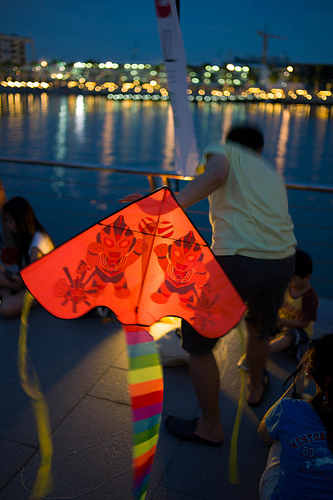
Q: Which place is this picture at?
A: It is at the shore.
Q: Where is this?
A: This is at the shore.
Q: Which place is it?
A: It is a shore.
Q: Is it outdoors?
A: Yes, it is outdoors.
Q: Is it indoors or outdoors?
A: It is outdoors.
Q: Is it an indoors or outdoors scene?
A: It is outdoors.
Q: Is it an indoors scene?
A: No, it is outdoors.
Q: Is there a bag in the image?
A: No, there are no bags.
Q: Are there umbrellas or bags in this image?
A: No, there are no bags or umbrellas.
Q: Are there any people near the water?
A: Yes, there are people near the water.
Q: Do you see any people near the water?
A: Yes, there are people near the water.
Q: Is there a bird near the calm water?
A: No, there are people near the water.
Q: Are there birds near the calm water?
A: No, there are people near the water.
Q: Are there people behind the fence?
A: Yes, there are people behind the fence.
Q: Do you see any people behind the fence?
A: Yes, there are people behind the fence.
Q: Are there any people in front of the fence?
A: No, the people are behind the fence.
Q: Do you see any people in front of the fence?
A: No, the people are behind the fence.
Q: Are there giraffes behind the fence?
A: No, there are people behind the fence.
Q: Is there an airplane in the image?
A: No, there are no airplanes.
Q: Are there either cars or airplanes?
A: No, there are no airplanes or cars.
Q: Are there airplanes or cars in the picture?
A: No, there are no airplanes or cars.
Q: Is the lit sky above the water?
A: Yes, the sky is above the water.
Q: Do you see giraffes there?
A: No, there are no giraffes.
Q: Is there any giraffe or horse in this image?
A: No, there are no giraffes or horses.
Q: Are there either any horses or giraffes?
A: No, there are no giraffes or horses.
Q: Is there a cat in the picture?
A: No, there are no cats.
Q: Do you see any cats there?
A: No, there are no cats.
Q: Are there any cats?
A: No, there are no cats.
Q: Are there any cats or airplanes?
A: No, there are no cats or airplanes.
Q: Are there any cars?
A: No, there are no cars.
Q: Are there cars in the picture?
A: No, there are no cars.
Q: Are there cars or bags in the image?
A: No, there are no cars or bags.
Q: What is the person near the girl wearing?
A: The person is wearing sandals.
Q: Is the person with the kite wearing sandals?
A: Yes, the person is wearing sandals.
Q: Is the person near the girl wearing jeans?
A: No, the person is wearing sandals.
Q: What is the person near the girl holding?
A: The person is holding the kite.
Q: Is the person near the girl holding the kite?
A: Yes, the person is holding the kite.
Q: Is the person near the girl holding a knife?
A: No, the person is holding the kite.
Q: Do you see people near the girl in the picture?
A: Yes, there is a person near the girl.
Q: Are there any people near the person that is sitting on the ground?
A: Yes, there is a person near the girl.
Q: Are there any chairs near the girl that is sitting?
A: No, there is a person near the girl.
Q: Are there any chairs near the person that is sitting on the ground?
A: No, there is a person near the girl.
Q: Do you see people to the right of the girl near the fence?
A: Yes, there is a person to the right of the girl.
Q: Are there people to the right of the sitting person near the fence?
A: Yes, there is a person to the right of the girl.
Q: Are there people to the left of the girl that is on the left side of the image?
A: No, the person is to the right of the girl.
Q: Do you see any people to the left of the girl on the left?
A: No, the person is to the right of the girl.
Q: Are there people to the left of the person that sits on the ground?
A: No, the person is to the right of the girl.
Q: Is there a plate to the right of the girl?
A: No, there is a person to the right of the girl.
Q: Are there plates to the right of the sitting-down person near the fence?
A: No, there is a person to the right of the girl.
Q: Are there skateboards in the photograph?
A: No, there are no skateboards.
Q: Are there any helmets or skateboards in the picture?
A: No, there are no skateboards or helmets.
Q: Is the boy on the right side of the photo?
A: Yes, the boy is on the right of the image.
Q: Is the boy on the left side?
A: No, the boy is on the right of the image.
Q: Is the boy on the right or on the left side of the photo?
A: The boy is on the right of the image.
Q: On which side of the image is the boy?
A: The boy is on the right of the image.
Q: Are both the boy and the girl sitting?
A: Yes, both the boy and the girl are sitting.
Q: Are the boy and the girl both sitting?
A: Yes, both the boy and the girl are sitting.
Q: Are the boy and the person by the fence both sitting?
A: Yes, both the boy and the girl are sitting.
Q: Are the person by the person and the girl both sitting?
A: Yes, both the boy and the girl are sitting.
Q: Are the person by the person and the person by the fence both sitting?
A: Yes, both the boy and the girl are sitting.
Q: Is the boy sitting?
A: Yes, the boy is sitting.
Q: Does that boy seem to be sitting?
A: Yes, the boy is sitting.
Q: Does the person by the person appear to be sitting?
A: Yes, the boy is sitting.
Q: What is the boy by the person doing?
A: The boy is sitting.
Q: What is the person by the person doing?
A: The boy is sitting.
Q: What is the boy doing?
A: The boy is sitting.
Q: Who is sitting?
A: The boy is sitting.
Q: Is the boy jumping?
A: No, the boy is sitting.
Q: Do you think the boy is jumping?
A: No, the boy is sitting.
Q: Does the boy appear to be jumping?
A: No, the boy is sitting.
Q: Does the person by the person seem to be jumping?
A: No, the boy is sitting.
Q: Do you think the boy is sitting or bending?
A: The boy is sitting.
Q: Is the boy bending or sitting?
A: The boy is sitting.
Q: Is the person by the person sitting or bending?
A: The boy is sitting.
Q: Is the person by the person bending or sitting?
A: The boy is sitting.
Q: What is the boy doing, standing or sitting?
A: The boy is sitting.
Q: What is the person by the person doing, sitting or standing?
A: The boy is sitting.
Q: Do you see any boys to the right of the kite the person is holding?
A: Yes, there is a boy to the right of the kite.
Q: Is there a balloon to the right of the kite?
A: No, there is a boy to the right of the kite.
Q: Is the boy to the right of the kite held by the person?
A: Yes, the boy is to the right of the kite.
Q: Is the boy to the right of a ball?
A: No, the boy is to the right of the kite.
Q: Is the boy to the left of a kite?
A: No, the boy is to the right of a kite.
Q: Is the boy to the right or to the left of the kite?
A: The boy is to the right of the kite.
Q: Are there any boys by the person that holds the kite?
A: Yes, there is a boy by the person.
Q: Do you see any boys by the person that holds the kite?
A: Yes, there is a boy by the person.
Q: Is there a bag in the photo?
A: No, there are no bags.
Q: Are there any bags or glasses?
A: No, there are no bags or glasses.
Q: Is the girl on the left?
A: Yes, the girl is on the left of the image.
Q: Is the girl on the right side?
A: No, the girl is on the left of the image.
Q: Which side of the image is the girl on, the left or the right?
A: The girl is on the left of the image.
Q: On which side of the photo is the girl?
A: The girl is on the left of the image.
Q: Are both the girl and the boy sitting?
A: Yes, both the girl and the boy are sitting.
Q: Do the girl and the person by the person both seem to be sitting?
A: Yes, both the girl and the boy are sitting.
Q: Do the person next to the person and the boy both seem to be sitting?
A: Yes, both the girl and the boy are sitting.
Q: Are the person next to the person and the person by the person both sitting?
A: Yes, both the girl and the boy are sitting.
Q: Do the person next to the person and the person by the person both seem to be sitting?
A: Yes, both the girl and the boy are sitting.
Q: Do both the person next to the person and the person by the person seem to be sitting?
A: Yes, both the girl and the boy are sitting.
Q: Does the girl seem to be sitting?
A: Yes, the girl is sitting.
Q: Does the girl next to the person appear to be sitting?
A: Yes, the girl is sitting.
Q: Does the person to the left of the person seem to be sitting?
A: Yes, the girl is sitting.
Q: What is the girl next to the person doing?
A: The girl is sitting.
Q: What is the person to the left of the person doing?
A: The girl is sitting.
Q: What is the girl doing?
A: The girl is sitting.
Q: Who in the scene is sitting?
A: The girl is sitting.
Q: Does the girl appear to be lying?
A: No, the girl is sitting.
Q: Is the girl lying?
A: No, the girl is sitting.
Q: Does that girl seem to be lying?
A: No, the girl is sitting.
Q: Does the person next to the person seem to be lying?
A: No, the girl is sitting.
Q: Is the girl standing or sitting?
A: The girl is sitting.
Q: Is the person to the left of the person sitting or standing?
A: The girl is sitting.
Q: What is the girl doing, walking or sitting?
A: The girl is sitting.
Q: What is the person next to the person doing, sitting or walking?
A: The girl is sitting.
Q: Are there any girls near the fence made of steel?
A: Yes, there is a girl near the fence.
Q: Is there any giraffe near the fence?
A: No, there is a girl near the fence.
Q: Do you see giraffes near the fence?
A: No, there is a girl near the fence.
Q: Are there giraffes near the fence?
A: No, there is a girl near the fence.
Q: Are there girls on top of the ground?
A: Yes, there is a girl on top of the ground.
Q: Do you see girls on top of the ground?
A: Yes, there is a girl on top of the ground.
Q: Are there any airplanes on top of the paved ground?
A: No, there is a girl on top of the ground.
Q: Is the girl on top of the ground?
A: Yes, the girl is on top of the ground.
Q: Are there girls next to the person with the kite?
A: Yes, there is a girl next to the person.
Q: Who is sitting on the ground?
A: The girl is sitting on the ground.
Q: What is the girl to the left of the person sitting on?
A: The girl is sitting on the ground.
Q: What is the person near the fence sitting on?
A: The girl is sitting on the ground.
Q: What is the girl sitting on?
A: The girl is sitting on the ground.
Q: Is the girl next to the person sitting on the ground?
A: Yes, the girl is sitting on the ground.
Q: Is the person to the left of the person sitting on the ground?
A: Yes, the girl is sitting on the ground.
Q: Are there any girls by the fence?
A: Yes, there is a girl by the fence.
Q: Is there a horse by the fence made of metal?
A: No, there is a girl by the fence.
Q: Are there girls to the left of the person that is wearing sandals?
A: Yes, there is a girl to the left of the person.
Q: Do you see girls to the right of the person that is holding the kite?
A: No, the girl is to the left of the person.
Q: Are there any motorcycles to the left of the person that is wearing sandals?
A: No, there is a girl to the left of the person.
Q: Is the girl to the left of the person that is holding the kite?
A: Yes, the girl is to the left of the person.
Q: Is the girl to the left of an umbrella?
A: No, the girl is to the left of the person.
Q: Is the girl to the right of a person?
A: No, the girl is to the left of a person.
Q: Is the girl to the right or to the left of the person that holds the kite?
A: The girl is to the left of the person.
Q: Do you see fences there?
A: Yes, there is a fence.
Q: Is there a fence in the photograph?
A: Yes, there is a fence.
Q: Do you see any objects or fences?
A: Yes, there is a fence.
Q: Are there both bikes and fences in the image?
A: No, there is a fence but no bikes.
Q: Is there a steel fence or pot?
A: Yes, there is a steel fence.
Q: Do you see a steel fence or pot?
A: Yes, there is a steel fence.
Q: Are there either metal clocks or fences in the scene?
A: Yes, there is a metal fence.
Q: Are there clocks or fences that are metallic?
A: Yes, the fence is metallic.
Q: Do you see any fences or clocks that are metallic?
A: Yes, the fence is metallic.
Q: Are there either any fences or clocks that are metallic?
A: Yes, the fence is metallic.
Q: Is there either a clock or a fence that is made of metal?
A: Yes, the fence is made of metal.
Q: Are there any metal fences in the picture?
A: Yes, there is a metal fence.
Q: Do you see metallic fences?
A: Yes, there is a metal fence.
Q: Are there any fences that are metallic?
A: Yes, there is a fence that is metallic.